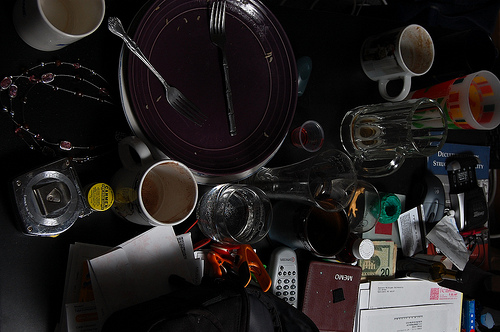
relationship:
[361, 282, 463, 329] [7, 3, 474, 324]
printed papers disarranged on table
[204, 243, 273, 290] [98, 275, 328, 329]
clips hanging from a bag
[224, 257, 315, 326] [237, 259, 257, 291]
bag with zip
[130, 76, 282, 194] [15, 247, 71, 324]
plate on table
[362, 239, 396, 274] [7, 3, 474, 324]
dollar bill laying on table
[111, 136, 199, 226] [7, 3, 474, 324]
cup on top of table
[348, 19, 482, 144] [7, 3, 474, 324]
dishes on top of table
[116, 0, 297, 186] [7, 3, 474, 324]
plate on top of table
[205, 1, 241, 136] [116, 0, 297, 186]
fork on top of plate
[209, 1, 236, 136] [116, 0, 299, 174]
fork sitting on plate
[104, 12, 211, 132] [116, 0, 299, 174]
fork sitting on plate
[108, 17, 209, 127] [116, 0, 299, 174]
fork sitting on plate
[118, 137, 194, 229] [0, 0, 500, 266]
cup sitting on a table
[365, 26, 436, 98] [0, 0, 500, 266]
cup sitting on a table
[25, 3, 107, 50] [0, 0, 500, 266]
cup sitting on a table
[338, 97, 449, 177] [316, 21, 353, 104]
beer mug sitting on a table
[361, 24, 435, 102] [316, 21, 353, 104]
cup sitting on a table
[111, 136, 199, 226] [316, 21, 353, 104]
cup sitting on a table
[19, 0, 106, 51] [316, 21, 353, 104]
cup sitting on a table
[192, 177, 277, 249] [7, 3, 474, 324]
glass sitting on table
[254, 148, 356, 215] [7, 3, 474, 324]
glass sitting on table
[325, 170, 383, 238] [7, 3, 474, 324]
glass sitting on table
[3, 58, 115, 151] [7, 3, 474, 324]
jewelry sitting on table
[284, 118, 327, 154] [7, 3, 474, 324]
shot glass sitting on a table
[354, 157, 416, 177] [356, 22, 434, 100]
handle of cup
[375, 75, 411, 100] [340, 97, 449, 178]
handle of beer mug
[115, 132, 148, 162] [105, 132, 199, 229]
handle of cup